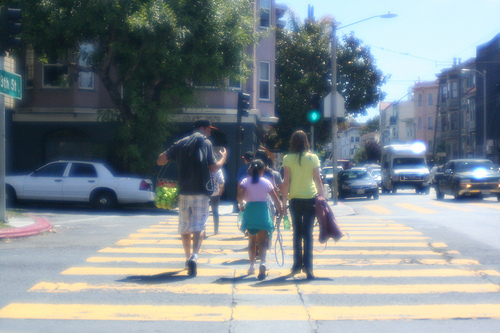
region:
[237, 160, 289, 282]
this is a little girl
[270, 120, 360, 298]
this is a woman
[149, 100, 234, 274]
this is a man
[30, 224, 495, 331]
white lines on street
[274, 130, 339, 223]
woman wearing a yellow shirt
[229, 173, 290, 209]
girl wearing a pink shirt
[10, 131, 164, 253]
this is white car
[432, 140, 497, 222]
this is a truck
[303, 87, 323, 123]
a traffic light on the intersection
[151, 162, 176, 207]
a basket of tennis balls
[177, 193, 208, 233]
a pair of plaid shorts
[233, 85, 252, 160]
a traffic light for the opposite direction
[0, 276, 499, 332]
a pedestrian crossing area on the street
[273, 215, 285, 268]
the girl is carrying a tennis racquet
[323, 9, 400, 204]
a traffic light along the street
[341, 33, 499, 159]
buildings along the street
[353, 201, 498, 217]
a pedestrian cross walk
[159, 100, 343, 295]
people crossing the street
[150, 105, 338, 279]
people crossing the street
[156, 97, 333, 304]
people crossing the street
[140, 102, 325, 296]
people crossing the street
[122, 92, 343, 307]
people crossing the street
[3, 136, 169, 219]
a white car is parked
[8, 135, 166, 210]
a white car is parked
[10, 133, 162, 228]
a white car is parked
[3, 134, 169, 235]
a white car is parked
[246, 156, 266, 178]
head of a person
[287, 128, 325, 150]
head of a person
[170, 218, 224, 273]
leg of a person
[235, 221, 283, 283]
leg of a person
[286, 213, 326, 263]
leg of a person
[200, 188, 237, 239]
leg of a person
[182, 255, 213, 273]
feet of a person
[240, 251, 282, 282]
feet of a person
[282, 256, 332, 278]
feet of a person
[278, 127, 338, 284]
PEDESTRIAN WALKING ON STREET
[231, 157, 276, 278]
CHILD WALKING WITH ADULTS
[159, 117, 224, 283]
PEDESTRIAN WALKING ON STREET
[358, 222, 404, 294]
PART OF CROSSWALK ON STREET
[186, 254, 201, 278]
FOOT OF PEDESTRIAN WALKING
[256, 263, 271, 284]
FOOT OF CHILD WALKING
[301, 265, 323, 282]
FOOT OF PERSON WALKING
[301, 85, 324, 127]
TRAFFIC GREEN STREET SIGNAL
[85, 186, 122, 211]
REAR WHEEL OF PARKED CAR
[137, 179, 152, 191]
REAR BRAKE LIGHT OF CAR